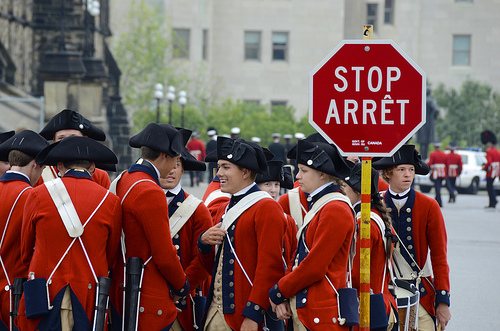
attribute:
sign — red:
[308, 41, 425, 157]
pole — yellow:
[351, 22, 381, 329]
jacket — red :
[17, 167, 125, 328]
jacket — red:
[279, 190, 353, 330]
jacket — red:
[209, 181, 283, 323]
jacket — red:
[113, 156, 194, 326]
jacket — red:
[102, 146, 182, 325]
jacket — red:
[14, 172, 119, 321]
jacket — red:
[111, 159, 183, 329]